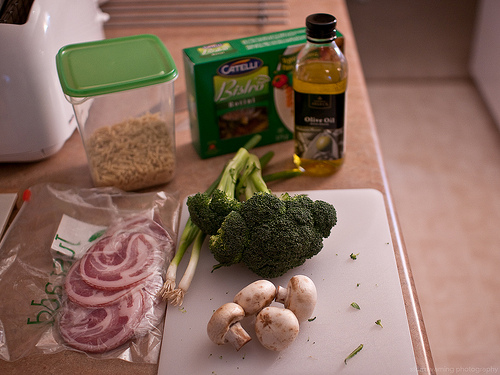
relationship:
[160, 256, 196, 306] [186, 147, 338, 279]
root ends of food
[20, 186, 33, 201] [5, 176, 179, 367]
slider closes packet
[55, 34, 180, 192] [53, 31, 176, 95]
container with lid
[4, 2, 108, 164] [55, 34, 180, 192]
toaster next to container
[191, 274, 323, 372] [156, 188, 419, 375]
mushrooms on board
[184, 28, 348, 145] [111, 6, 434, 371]
box on table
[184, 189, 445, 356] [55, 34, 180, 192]
board on container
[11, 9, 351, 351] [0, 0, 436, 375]
food sitting on counter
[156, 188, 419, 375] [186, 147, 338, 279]
board with food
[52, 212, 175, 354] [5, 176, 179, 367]
raw meat in packet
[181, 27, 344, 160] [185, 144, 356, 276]
box of food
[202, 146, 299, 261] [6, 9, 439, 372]
food sitting on counter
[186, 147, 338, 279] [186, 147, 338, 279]
food of food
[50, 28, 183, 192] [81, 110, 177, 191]
container of pasta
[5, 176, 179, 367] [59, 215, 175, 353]
packet of raw meat